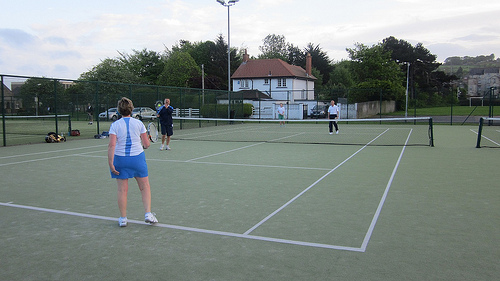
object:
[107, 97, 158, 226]
woman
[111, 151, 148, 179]
shorts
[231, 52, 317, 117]
house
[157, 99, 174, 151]
man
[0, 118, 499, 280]
court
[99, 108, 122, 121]
cars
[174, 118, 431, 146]
net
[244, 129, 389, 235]
lines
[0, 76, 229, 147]
fence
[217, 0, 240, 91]
lamp